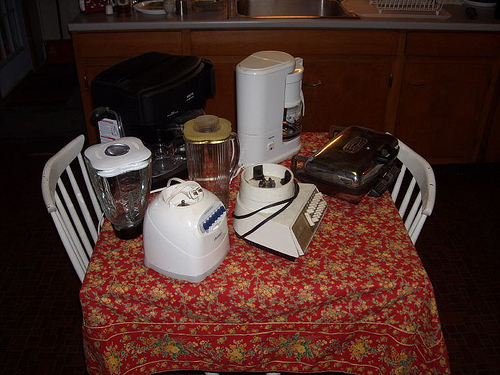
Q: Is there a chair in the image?
A: Yes, there is a chair.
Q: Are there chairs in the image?
A: Yes, there is a chair.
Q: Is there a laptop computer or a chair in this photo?
A: Yes, there is a chair.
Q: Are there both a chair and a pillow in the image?
A: No, there is a chair but no pillows.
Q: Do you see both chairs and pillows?
A: No, there is a chair but no pillows.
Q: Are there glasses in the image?
A: No, there are no glasses.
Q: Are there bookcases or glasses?
A: No, there are no glasses or bookcases.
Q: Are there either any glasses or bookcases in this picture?
A: No, there are no glasses or bookcases.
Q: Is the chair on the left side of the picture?
A: Yes, the chair is on the left of the image.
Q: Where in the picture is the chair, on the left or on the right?
A: The chair is on the left of the image.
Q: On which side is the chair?
A: The chair is on the left of the image.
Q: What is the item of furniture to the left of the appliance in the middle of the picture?
A: The piece of furniture is a chair.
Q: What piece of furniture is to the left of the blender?
A: The piece of furniture is a chair.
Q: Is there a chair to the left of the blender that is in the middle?
A: Yes, there is a chair to the left of the blender.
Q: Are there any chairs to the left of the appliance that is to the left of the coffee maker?
A: Yes, there is a chair to the left of the blender.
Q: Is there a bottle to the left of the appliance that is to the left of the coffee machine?
A: No, there is a chair to the left of the blender.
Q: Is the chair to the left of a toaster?
A: No, the chair is to the left of a blender.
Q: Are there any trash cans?
A: No, there are no trash cans.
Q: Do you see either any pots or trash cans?
A: No, there are no trash cans or pots.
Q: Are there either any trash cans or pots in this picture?
A: No, there are no trash cans or pots.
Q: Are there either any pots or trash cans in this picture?
A: No, there are no trash cans or pots.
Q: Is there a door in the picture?
A: Yes, there is a door.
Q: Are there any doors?
A: Yes, there is a door.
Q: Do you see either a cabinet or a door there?
A: Yes, there is a door.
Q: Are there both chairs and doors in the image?
A: Yes, there are both a door and a chair.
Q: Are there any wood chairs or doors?
A: Yes, there is a wood door.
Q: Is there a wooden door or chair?
A: Yes, there is a wood door.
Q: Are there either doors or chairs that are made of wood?
A: Yes, the door is made of wood.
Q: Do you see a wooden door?
A: Yes, there is a wood door.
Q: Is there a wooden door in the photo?
A: Yes, there is a wood door.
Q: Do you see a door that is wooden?
A: Yes, there is a door that is wooden.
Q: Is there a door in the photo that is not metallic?
A: Yes, there is a wooden door.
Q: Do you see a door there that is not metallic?
A: Yes, there is a wooden door.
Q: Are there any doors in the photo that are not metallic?
A: Yes, there is a wooden door.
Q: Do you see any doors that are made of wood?
A: Yes, there is a door that is made of wood.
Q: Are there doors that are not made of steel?
A: Yes, there is a door that is made of wood.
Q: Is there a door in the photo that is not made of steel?
A: Yes, there is a door that is made of wood.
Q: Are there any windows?
A: No, there are no windows.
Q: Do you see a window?
A: No, there are no windows.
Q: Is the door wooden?
A: Yes, the door is wooden.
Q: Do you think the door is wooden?
A: Yes, the door is wooden.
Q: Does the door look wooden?
A: Yes, the door is wooden.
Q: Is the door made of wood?
A: Yes, the door is made of wood.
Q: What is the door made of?
A: The door is made of wood.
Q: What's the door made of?
A: The door is made of wood.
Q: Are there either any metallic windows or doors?
A: No, there is a door but it is wooden.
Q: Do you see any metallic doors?
A: No, there is a door but it is wooden.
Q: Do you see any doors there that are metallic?
A: No, there is a door but it is wooden.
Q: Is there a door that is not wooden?
A: No, there is a door but it is wooden.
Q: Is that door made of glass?
A: No, the door is made of wood.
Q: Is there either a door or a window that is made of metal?
A: No, there is a door but it is made of wood.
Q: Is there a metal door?
A: No, there is a door but it is made of wood.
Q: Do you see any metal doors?
A: No, there is a door but it is made of wood.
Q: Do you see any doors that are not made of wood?
A: No, there is a door but it is made of wood.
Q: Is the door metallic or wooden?
A: The door is wooden.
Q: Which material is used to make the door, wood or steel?
A: The door is made of wood.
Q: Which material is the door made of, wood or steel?
A: The door is made of wood.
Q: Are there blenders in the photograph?
A: Yes, there is a blender.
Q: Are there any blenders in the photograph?
A: Yes, there is a blender.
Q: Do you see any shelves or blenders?
A: Yes, there is a blender.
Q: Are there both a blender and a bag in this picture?
A: No, there is a blender but no bags.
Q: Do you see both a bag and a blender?
A: No, there is a blender but no bags.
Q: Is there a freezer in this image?
A: No, there are no refrigerators.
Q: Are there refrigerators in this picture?
A: No, there are no refrigerators.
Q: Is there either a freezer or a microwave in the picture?
A: No, there are no refrigerators or microwaves.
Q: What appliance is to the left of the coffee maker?
A: The appliance is a blender.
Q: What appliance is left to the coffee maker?
A: The appliance is a blender.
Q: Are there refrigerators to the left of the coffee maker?
A: No, there is a blender to the left of the coffee maker.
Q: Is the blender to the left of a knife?
A: No, the blender is to the left of the coffee maker.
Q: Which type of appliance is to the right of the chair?
A: The appliance is a blender.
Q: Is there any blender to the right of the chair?
A: Yes, there is a blender to the right of the chair.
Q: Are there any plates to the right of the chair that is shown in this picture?
A: No, there is a blender to the right of the chair.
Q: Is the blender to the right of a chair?
A: Yes, the blender is to the right of a chair.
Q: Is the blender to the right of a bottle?
A: No, the blender is to the right of a chair.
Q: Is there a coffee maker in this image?
A: Yes, there is a coffee maker.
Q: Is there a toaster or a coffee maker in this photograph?
A: Yes, there is a coffee maker.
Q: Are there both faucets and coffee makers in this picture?
A: No, there is a coffee maker but no faucets.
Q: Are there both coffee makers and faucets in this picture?
A: No, there is a coffee maker but no faucets.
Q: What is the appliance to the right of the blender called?
A: The appliance is a coffee maker.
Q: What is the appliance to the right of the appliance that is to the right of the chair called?
A: The appliance is a coffee maker.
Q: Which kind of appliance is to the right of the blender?
A: The appliance is a coffee maker.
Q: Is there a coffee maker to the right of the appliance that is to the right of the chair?
A: Yes, there is a coffee maker to the right of the blender.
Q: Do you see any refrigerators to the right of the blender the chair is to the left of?
A: No, there is a coffee maker to the right of the blender.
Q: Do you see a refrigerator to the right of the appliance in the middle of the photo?
A: No, there is a coffee maker to the right of the blender.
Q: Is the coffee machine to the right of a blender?
A: Yes, the coffee machine is to the right of a blender.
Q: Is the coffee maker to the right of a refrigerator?
A: No, the coffee maker is to the right of a blender.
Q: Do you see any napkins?
A: No, there are no napkins.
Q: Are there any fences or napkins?
A: No, there are no napkins or fences.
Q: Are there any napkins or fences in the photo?
A: No, there are no napkins or fences.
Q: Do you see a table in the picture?
A: Yes, there is a table.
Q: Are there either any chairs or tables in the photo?
A: Yes, there is a table.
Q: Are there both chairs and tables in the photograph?
A: Yes, there are both a table and a chair.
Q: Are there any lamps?
A: No, there are no lamps.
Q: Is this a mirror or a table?
A: This is a table.